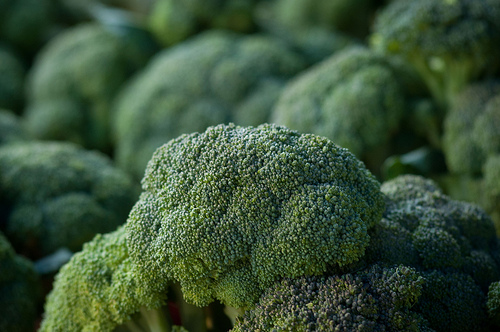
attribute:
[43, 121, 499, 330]
brocolli — purple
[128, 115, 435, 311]
brocolli — green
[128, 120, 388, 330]
broccoli — green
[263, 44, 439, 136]
broccoli — top, stem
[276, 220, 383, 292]
stem — broccoli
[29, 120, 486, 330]
broccoli — head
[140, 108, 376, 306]
broccoli — large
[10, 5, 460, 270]
broccoli — green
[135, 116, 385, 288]
broccoli — large